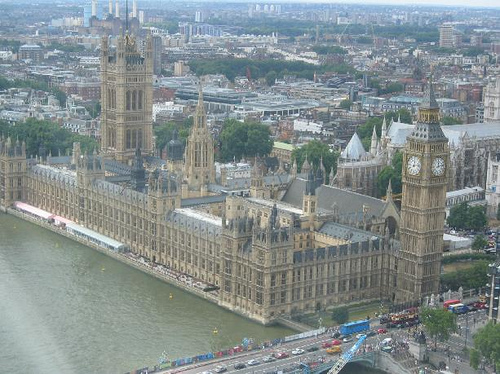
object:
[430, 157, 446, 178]
clock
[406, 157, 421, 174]
clock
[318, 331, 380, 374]
crane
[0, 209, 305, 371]
water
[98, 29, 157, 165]
tower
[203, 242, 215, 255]
windows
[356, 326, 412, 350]
ground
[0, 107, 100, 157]
trees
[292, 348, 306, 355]
car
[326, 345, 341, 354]
car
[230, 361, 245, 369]
car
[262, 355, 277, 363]
car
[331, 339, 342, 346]
car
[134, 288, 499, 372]
highway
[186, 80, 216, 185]
tower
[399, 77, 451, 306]
clock tower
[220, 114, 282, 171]
trees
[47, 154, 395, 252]
rooftop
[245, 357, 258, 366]
cars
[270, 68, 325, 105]
ground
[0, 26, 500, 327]
buildings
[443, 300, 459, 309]
bus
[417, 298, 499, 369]
trees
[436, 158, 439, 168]
hand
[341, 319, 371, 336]
bus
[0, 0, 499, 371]
photo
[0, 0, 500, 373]
city